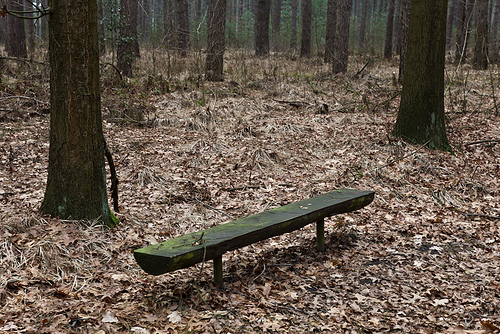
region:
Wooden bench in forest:
[131, 185, 378, 275]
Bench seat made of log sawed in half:
[130, 184, 377, 274]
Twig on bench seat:
[173, 227, 211, 274]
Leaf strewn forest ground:
[1, 53, 495, 330]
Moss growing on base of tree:
[96, 185, 116, 225]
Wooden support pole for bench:
[208, 253, 226, 290]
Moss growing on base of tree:
[423, 112, 453, 154]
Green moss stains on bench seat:
[135, 210, 287, 253]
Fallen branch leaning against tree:
[101, 130, 121, 215]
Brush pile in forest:
[1, 49, 61, 121]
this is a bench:
[144, 158, 404, 273]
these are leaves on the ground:
[329, 227, 371, 287]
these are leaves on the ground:
[358, 222, 429, 284]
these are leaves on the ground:
[209, 118, 280, 188]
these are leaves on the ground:
[186, 124, 236, 179]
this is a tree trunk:
[18, 18, 130, 238]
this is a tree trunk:
[113, 5, 148, 71]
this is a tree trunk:
[198, 13, 239, 83]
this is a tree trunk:
[242, 5, 277, 57]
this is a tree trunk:
[383, 5, 477, 164]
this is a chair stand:
[207, 258, 228, 292]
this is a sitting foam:
[140, 188, 371, 274]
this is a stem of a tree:
[51, 11, 96, 202]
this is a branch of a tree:
[11, 3, 49, 18]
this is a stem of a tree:
[407, 21, 454, 157]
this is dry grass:
[175, 95, 368, 179]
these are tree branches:
[112, 18, 243, 78]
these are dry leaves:
[336, 273, 440, 321]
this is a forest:
[21, 0, 473, 289]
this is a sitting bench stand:
[319, 224, 340, 256]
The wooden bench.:
[130, 187, 375, 271]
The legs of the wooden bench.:
[205, 222, 338, 284]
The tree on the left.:
[42, 1, 114, 218]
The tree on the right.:
[405, 4, 452, 155]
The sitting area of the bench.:
[127, 181, 380, 266]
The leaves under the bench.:
[154, 223, 352, 298]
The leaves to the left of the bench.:
[10, 213, 143, 333]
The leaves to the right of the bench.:
[360, 166, 464, 256]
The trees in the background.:
[42, 2, 498, 87]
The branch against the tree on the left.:
[101, 139, 124, 219]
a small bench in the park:
[86, 149, 459, 320]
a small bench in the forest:
[107, 182, 412, 314]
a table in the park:
[124, 175, 413, 290]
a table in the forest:
[112, 136, 437, 281]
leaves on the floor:
[269, 264, 362, 332]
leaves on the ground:
[408, 197, 483, 272]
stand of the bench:
[201, 253, 237, 285]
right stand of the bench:
[311, 220, 346, 269]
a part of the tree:
[94, 135, 145, 212]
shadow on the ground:
[293, 250, 312, 279]